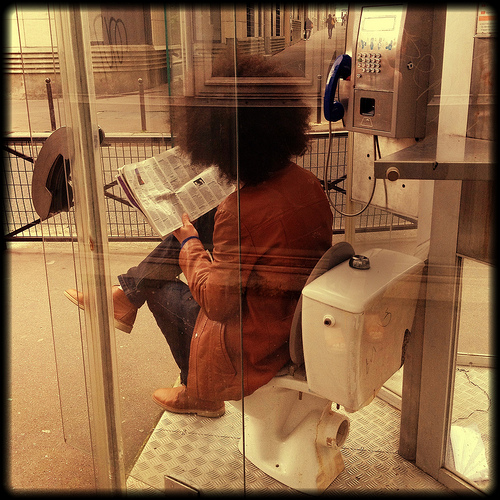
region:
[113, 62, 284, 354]
this is a lady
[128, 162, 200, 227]
the lady is reading a magazine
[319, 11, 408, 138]
this is a telephone booth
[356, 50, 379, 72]
these are the buttons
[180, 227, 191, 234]
the lady has a light skin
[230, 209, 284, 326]
this is a pullover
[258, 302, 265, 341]
the pullover is brown in color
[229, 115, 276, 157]
the lady has along hair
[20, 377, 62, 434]
this is the floor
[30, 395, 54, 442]
the floor is made of stones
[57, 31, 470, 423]
woman seated in glass cubicle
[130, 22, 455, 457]
toilet below public telephone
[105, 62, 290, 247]
woman reading a newspaper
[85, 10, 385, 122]
person walking down sidewalk toward booth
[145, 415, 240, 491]
diamond pattern on metal floor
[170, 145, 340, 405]
woman wearing long brown leather jacket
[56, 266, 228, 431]
feet in brown ankle boots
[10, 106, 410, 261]
metal fence in back of glass booth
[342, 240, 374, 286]
silver knob on top of toilet tank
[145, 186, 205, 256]
thumb on top of newsprint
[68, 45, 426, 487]
a fully dressed person sits on a toilet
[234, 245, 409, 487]
the toilet is not connected to anything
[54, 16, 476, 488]
the person on the toilet is in a telephone booth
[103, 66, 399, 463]
the person reads a newspaper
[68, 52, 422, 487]
the person on the toilet reads a newspaper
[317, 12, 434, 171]
a telephone hangs on the wall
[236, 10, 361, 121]
people in an allyway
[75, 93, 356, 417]
the person is wearing brown shoes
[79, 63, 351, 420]
the person wears a brown leather coat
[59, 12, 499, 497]
a phone booth with a metal floor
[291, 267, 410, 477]
the toilet is white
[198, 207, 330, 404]
the jacket is brown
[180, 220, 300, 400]
the jacket is made of leather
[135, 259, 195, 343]
the jeans are blue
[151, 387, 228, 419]
the shoes are brown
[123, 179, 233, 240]
the newspaper is white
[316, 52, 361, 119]
the telephone is blue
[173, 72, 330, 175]
the hair is black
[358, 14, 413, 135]
the telephone is silver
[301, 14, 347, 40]
people are walking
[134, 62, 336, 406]
one man is sitting in the toilet.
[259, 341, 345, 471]
toilet is white color.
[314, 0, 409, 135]
one public telephone is seen.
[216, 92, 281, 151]
Hair is black color.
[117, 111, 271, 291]
man is reading newspaper.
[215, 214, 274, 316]
Man is wearing brown jacket.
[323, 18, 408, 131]
Phone is grey and blue color.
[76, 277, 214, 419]
Shoe is brown color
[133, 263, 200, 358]
man pant is blue color.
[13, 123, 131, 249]
Fence is silver color.